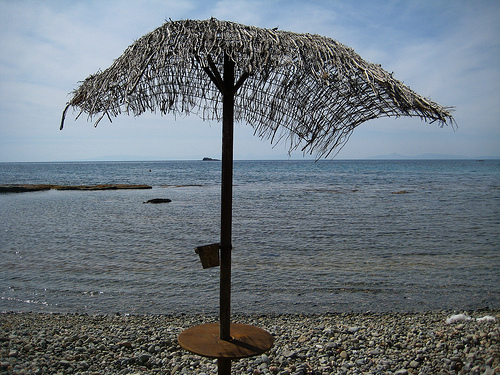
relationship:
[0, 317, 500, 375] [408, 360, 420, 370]
rock lying next to rock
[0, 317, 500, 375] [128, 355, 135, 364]
rock lying next to rock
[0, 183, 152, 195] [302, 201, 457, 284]
land protusion jutting into water